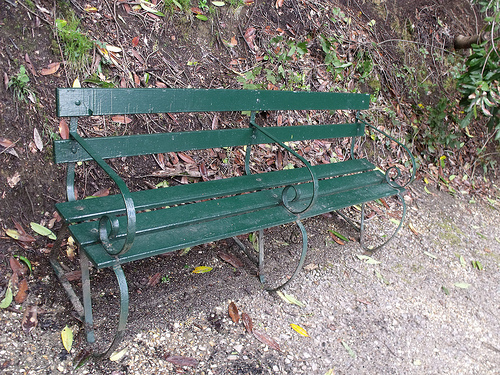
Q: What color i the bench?
A: Green.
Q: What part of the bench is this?
A: Back.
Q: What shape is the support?
A: Curved.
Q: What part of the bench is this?
A: Seat.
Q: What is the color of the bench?
A: Green.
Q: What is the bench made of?
A: Metal.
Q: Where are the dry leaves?
A: Behind the bench.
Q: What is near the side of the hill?
A: Bench.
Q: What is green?
A: The bench.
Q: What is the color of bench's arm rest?
A: Green.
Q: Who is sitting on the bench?
A: No one.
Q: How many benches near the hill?
A: One.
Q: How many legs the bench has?
A: Three.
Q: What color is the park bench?
A: Green.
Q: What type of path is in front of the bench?
A: Gravel.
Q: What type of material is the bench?
A: Wood and metal.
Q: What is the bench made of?
A: Wood.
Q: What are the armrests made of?
A: Metal.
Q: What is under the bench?
A: Dirt.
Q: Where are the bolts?
A: In the bench.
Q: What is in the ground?
A: Rocks.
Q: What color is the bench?
A: Green.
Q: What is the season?
A: Early autumn.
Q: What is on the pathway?
A: Gravel.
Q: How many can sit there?
A: Up to 4.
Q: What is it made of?
A: Metal and wood.